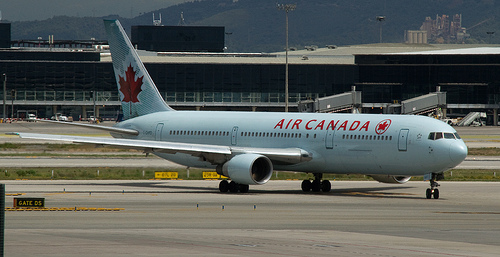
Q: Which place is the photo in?
A: It is at the runway.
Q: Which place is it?
A: It is a runway.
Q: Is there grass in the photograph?
A: Yes, there is grass.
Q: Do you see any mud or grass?
A: Yes, there is grass.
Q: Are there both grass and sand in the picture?
A: No, there is grass but no sand.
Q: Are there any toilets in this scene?
A: No, there are no toilets.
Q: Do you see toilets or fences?
A: No, there are no toilets or fences.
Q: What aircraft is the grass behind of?
A: The grass is behind the airplane.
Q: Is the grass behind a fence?
A: No, the grass is behind the airplane.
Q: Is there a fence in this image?
A: No, there are no fences.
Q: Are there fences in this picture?
A: No, there are no fences.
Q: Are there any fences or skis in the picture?
A: No, there are no fences or skis.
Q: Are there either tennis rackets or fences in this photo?
A: No, there are no fences or tennis rackets.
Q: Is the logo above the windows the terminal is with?
A: Yes, the logo is above the windows.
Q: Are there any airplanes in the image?
A: Yes, there is an airplane.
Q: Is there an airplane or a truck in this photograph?
A: Yes, there is an airplane.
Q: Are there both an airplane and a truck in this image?
A: No, there is an airplane but no trucks.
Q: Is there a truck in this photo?
A: No, there are no trucks.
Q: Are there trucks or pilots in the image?
A: No, there are no trucks or pilots.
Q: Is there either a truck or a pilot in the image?
A: No, there are no trucks or pilots.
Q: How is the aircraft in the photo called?
A: The aircraft is an airplane.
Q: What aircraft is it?
A: The aircraft is an airplane.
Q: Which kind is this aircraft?
A: That is an airplane.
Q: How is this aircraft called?
A: That is an airplane.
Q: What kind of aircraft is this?
A: That is an airplane.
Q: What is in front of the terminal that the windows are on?
A: The airplane is in front of the terminal.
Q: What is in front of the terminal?
A: The airplane is in front of the terminal.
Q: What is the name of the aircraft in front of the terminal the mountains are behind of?
A: The aircraft is an airplane.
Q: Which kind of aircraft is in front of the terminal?
A: The aircraft is an airplane.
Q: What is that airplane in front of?
A: The airplane is in front of the terminal.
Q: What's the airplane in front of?
A: The airplane is in front of the terminal.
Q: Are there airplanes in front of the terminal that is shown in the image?
A: Yes, there is an airplane in front of the terminal.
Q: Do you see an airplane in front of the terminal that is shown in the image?
A: Yes, there is an airplane in front of the terminal.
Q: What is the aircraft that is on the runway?
A: The aircraft is an airplane.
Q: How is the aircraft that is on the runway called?
A: The aircraft is an airplane.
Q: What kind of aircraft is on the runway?
A: The aircraft is an airplane.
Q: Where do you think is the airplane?
A: The airplane is on the runway.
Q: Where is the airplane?
A: The airplane is on the runway.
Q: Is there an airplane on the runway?
A: Yes, there is an airplane on the runway.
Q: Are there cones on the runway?
A: No, there is an airplane on the runway.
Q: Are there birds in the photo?
A: No, there are no birds.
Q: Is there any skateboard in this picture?
A: No, there are no skateboards.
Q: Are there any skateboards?
A: No, there are no skateboards.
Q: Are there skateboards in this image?
A: No, there are no skateboards.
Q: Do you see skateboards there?
A: No, there are no skateboards.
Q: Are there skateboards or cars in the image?
A: No, there are no skateboards or cars.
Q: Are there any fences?
A: No, there are no fences.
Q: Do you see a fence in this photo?
A: No, there are no fences.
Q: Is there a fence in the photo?
A: No, there are no fences.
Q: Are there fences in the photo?
A: No, there are no fences.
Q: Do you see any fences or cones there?
A: No, there are no fences or cones.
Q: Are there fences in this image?
A: No, there are no fences.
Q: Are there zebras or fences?
A: No, there are no fences or zebras.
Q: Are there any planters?
A: No, there are no planters.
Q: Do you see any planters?
A: No, there are no planters.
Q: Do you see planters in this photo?
A: No, there are no planters.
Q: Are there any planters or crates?
A: No, there are no planters or crates.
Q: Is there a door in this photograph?
A: Yes, there is a door.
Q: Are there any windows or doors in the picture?
A: Yes, there is a door.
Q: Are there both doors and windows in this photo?
A: Yes, there are both a door and a window.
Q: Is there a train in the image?
A: No, there are no trains.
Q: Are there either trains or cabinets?
A: No, there are no trains or cabinets.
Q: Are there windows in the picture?
A: Yes, there are windows.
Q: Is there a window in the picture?
A: Yes, there are windows.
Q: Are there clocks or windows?
A: Yes, there are windows.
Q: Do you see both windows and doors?
A: Yes, there are both windows and a door.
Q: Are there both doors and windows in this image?
A: Yes, there are both windows and a door.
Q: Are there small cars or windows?
A: Yes, there are small windows.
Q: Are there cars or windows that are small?
A: Yes, the windows are small.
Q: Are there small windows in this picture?
A: Yes, there are small windows.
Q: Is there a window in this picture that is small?
A: Yes, there are windows that are small.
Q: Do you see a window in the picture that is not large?
A: Yes, there are small windows.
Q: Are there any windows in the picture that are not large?
A: Yes, there are small windows.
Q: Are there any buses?
A: No, there are no buses.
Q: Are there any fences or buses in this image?
A: No, there are no buses or fences.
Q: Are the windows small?
A: Yes, the windows are small.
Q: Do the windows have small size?
A: Yes, the windows are small.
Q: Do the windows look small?
A: Yes, the windows are small.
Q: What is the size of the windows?
A: The windows are small.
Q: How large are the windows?
A: The windows are small.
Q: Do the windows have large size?
A: No, the windows are small.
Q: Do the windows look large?
A: No, the windows are small.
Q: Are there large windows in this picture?
A: No, there are windows but they are small.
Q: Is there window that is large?
A: No, there are windows but they are small.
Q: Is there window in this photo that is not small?
A: No, there are windows but they are small.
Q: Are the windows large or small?
A: The windows are small.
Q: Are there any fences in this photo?
A: No, there are no fences.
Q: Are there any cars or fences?
A: No, there are no fences or cars.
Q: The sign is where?
A: The sign is on the runway.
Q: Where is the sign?
A: The sign is on the runway.